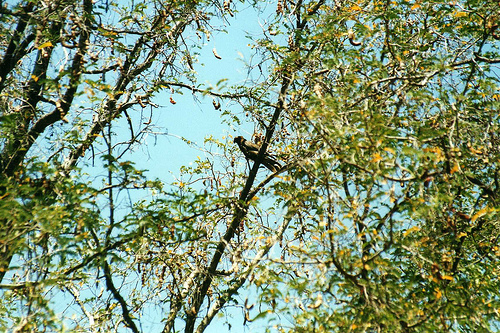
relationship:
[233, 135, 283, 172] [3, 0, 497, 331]
bird in tree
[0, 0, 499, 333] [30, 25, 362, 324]
leaves on tree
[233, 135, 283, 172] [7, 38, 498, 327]
bird in tree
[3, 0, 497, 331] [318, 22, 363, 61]
tree with leaves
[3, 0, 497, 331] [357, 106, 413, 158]
tree with leaves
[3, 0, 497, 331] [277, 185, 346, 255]
tree with leaves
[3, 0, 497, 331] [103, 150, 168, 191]
tree with leaves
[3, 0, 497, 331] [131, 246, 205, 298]
tree with leaves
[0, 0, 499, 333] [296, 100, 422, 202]
tree with leaves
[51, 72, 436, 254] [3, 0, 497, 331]
leaves on tree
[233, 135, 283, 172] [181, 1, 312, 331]
bird on branch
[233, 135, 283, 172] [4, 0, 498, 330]
bird in trees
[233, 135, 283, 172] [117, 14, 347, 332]
bird in tree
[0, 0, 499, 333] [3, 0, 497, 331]
leaves in tree